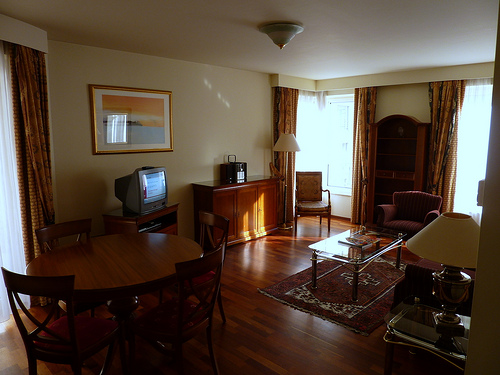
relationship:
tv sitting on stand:
[117, 168, 168, 206] [108, 208, 175, 234]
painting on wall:
[89, 84, 173, 152] [44, 40, 282, 251]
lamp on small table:
[403, 212, 472, 325] [385, 296, 471, 371]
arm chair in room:
[373, 190, 438, 234] [3, 1, 500, 373]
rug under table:
[263, 252, 418, 338] [306, 223, 407, 298]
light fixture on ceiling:
[259, 23, 300, 49] [1, 2, 497, 73]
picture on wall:
[89, 84, 173, 152] [44, 40, 282, 251]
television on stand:
[117, 168, 168, 206] [108, 208, 175, 234]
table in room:
[26, 239, 211, 299] [3, 1, 500, 373]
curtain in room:
[7, 48, 57, 304] [3, 1, 500, 373]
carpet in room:
[263, 252, 418, 338] [3, 1, 500, 373]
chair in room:
[291, 170, 335, 227] [3, 1, 500, 373]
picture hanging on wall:
[89, 84, 173, 152] [44, 40, 282, 251]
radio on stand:
[224, 163, 249, 181] [196, 178, 286, 241]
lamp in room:
[275, 133, 295, 230] [3, 1, 500, 373]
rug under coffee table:
[263, 252, 418, 338] [306, 223, 407, 298]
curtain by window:
[275, 90, 297, 226] [290, 102, 356, 189]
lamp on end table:
[403, 212, 472, 325] [385, 296, 471, 371]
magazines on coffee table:
[343, 230, 375, 249] [306, 223, 407, 298]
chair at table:
[3, 269, 118, 374] [26, 239, 211, 299]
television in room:
[117, 168, 168, 206] [3, 1, 500, 373]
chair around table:
[198, 212, 229, 321] [26, 239, 211, 299]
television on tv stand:
[117, 168, 168, 206] [108, 208, 175, 234]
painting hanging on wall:
[89, 84, 173, 152] [44, 40, 282, 251]